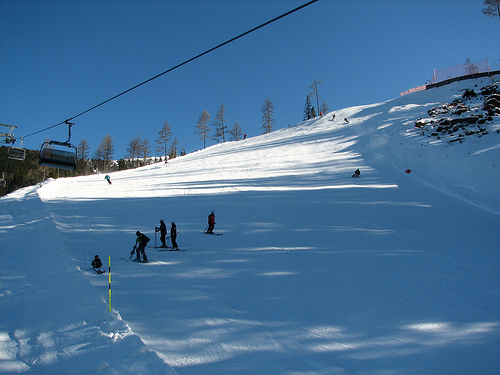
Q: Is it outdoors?
A: Yes, it is outdoors.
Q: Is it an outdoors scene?
A: Yes, it is outdoors.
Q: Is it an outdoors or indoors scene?
A: It is outdoors.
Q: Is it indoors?
A: No, it is outdoors.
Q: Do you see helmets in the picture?
A: No, there are no helmets.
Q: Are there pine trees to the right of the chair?
A: Yes, there is a pine tree to the right of the chair.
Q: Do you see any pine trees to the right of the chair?
A: Yes, there is a pine tree to the right of the chair.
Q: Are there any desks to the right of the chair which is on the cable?
A: No, there is a pine tree to the right of the chair.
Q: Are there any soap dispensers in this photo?
A: No, there are no soap dispensers.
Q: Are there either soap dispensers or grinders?
A: No, there are no soap dispensers or grinders.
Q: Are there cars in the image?
A: No, there are no cars.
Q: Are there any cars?
A: No, there are no cars.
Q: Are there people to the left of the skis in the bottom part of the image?
A: Yes, there are people to the left of the skis.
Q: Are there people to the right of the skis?
A: No, the people are to the left of the skis.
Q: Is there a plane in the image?
A: No, there are no airplanes.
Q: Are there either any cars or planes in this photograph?
A: No, there are no planes or cars.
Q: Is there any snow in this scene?
A: Yes, there is snow.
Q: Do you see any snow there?
A: Yes, there is snow.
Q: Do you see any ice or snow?
A: Yes, there is snow.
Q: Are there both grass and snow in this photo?
A: No, there is snow but no grass.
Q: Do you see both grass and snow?
A: No, there is snow but no grass.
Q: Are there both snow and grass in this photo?
A: No, there is snow but no grass.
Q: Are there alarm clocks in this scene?
A: No, there are no alarm clocks.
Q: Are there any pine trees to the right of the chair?
A: Yes, there is a pine tree to the right of the chair.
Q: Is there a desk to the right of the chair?
A: No, there is a pine tree to the right of the chair.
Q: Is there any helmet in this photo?
A: No, there are no helmets.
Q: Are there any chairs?
A: Yes, there is a chair.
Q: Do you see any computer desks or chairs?
A: Yes, there is a chair.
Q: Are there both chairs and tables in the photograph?
A: No, there is a chair but no tables.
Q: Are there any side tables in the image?
A: No, there are no side tables.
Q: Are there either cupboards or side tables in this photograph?
A: No, there are no side tables or cupboards.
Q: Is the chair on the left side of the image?
A: Yes, the chair is on the left of the image.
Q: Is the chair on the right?
A: No, the chair is on the left of the image.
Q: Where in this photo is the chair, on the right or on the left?
A: The chair is on the left of the image.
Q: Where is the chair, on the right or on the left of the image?
A: The chair is on the left of the image.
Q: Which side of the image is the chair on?
A: The chair is on the left of the image.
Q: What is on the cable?
A: The chair is on the cable.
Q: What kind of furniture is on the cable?
A: The piece of furniture is a chair.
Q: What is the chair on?
A: The chair is on the cable.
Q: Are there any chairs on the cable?
A: Yes, there is a chair on the cable.